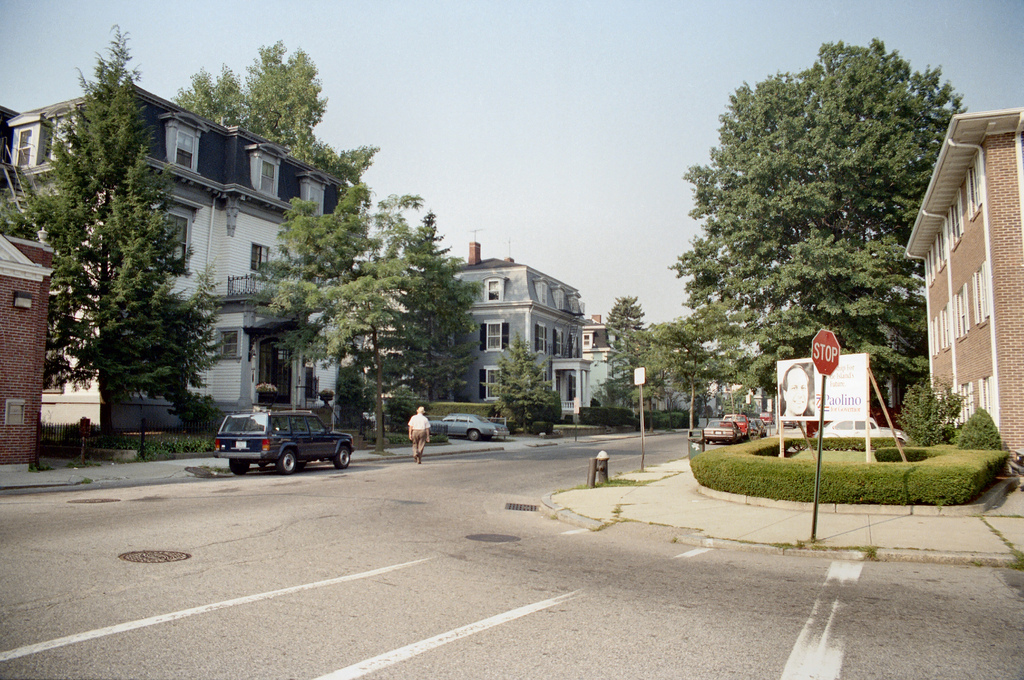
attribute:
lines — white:
[760, 551, 903, 662]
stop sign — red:
[803, 322, 849, 403]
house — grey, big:
[427, 247, 613, 425]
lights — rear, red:
[207, 430, 279, 456]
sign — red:
[779, 307, 868, 401]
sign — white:
[745, 346, 910, 446]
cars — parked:
[661, 392, 804, 479]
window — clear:
[458, 283, 549, 305]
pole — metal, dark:
[809, 374, 831, 537]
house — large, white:
[1, 86, 351, 411]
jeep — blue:
[206, 404, 353, 476]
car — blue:
[413, 413, 511, 439]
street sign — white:
[627, 361, 651, 461]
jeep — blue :
[223, 399, 351, 482]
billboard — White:
[771, 351, 871, 442]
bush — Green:
[955, 405, 1007, 451]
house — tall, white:
[7, 85, 362, 453]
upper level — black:
[9, 81, 349, 216]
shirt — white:
[408, 413, 430, 431]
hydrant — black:
[594, 458, 607, 485]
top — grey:
[596, 450, 607, 463]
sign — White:
[769, 357, 906, 463]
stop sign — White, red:
[812, 327, 843, 375]